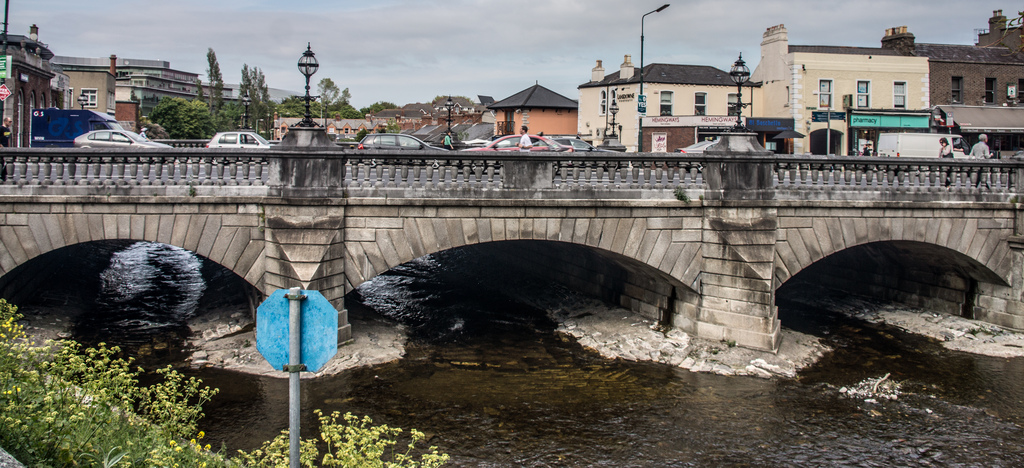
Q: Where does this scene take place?
A: Near an aquaduct.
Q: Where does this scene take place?
A: City bridge.